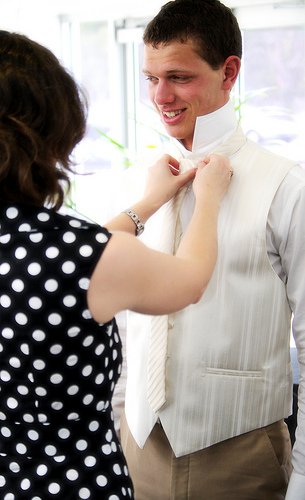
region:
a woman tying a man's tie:
[1, 6, 303, 440]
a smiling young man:
[128, 8, 304, 451]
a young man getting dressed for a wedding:
[134, 13, 304, 468]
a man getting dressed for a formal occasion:
[127, 6, 290, 498]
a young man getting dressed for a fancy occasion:
[47, 0, 304, 478]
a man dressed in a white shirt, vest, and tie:
[113, 0, 303, 439]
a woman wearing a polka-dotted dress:
[0, 37, 145, 489]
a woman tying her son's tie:
[1, 24, 304, 499]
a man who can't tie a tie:
[105, 0, 304, 498]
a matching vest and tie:
[110, 146, 301, 466]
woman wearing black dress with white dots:
[0, 21, 150, 498]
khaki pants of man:
[118, 414, 295, 497]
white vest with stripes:
[125, 160, 298, 444]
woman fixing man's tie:
[0, 27, 233, 499]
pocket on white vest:
[193, 355, 269, 393]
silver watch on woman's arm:
[121, 204, 144, 235]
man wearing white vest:
[108, 3, 302, 496]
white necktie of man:
[139, 154, 199, 408]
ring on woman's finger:
[226, 167, 237, 180]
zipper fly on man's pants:
[164, 439, 191, 497]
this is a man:
[106, 0, 293, 496]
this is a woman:
[0, 28, 227, 492]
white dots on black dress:
[10, 424, 79, 485]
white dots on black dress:
[24, 369, 67, 408]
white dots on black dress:
[21, 264, 64, 313]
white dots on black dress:
[4, 301, 33, 345]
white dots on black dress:
[94, 475, 115, 496]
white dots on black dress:
[85, 389, 103, 418]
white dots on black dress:
[12, 470, 36, 496]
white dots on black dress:
[59, 257, 86, 295]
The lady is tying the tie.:
[122, 149, 238, 211]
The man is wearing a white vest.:
[126, 169, 286, 388]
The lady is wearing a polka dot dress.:
[12, 294, 73, 394]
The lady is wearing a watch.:
[119, 194, 155, 241]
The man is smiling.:
[139, 88, 220, 132]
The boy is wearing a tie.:
[151, 155, 180, 344]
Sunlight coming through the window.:
[70, 21, 285, 148]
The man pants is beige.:
[116, 425, 281, 498]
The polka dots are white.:
[20, 358, 88, 409]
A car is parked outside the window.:
[235, 93, 301, 151]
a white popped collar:
[163, 100, 237, 149]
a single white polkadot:
[90, 472, 113, 488]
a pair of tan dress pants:
[114, 417, 295, 499]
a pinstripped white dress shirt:
[121, 117, 304, 451]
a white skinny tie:
[140, 156, 201, 413]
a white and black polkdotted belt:
[0, 405, 125, 464]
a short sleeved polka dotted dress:
[0, 201, 136, 499]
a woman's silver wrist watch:
[120, 207, 147, 236]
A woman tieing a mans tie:
[0, 1, 304, 498]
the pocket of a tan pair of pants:
[258, 422, 292, 473]